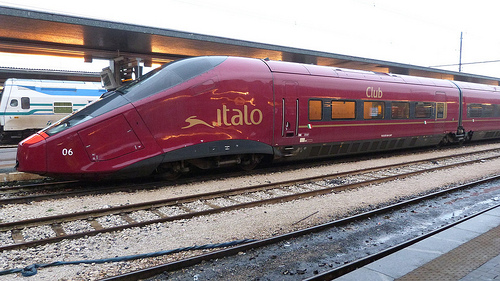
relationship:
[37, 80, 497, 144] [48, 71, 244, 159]
train has nose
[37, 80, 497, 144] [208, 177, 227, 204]
train on tracks